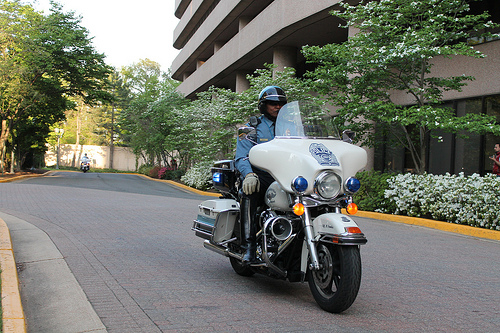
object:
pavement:
[16, 159, 157, 327]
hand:
[240, 172, 262, 195]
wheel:
[302, 240, 365, 314]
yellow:
[377, 214, 488, 239]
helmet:
[257, 84, 288, 119]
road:
[32, 166, 151, 314]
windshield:
[274, 97, 342, 140]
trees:
[298, 0, 498, 173]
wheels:
[222, 195, 259, 277]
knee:
[239, 180, 261, 202]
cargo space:
[193, 199, 237, 246]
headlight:
[316, 171, 343, 202]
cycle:
[192, 100, 367, 315]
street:
[2, 166, 498, 331]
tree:
[0, 0, 97, 172]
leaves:
[45, 1, 69, 24]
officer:
[230, 85, 312, 269]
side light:
[291, 203, 305, 217]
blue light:
[294, 176, 310, 193]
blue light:
[346, 177, 363, 193]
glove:
[241, 171, 262, 196]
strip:
[382, 214, 497, 240]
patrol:
[222, 72, 402, 310]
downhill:
[77, 170, 227, 304]